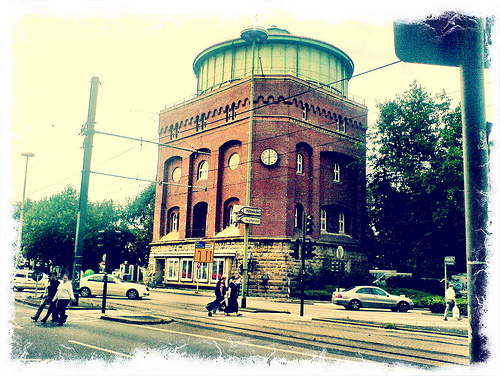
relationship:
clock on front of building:
[262, 147, 279, 168] [143, 23, 367, 299]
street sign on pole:
[232, 205, 262, 227] [240, 223, 250, 308]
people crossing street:
[32, 273, 75, 325] [13, 290, 471, 369]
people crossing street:
[207, 275, 242, 316] [13, 290, 471, 369]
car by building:
[331, 283, 414, 311] [143, 23, 367, 299]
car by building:
[79, 273, 151, 300] [143, 23, 367, 299]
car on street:
[331, 283, 414, 311] [13, 290, 471, 369]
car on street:
[79, 273, 151, 300] [13, 290, 471, 369]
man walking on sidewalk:
[441, 281, 460, 322] [313, 312, 473, 336]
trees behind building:
[13, 79, 463, 288] [143, 23, 367, 299]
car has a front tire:
[331, 283, 414, 311] [391, 302, 408, 313]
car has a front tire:
[79, 273, 151, 300] [127, 289, 141, 300]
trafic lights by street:
[290, 215, 317, 261] [13, 290, 471, 369]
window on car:
[357, 286, 386, 298] [331, 283, 414, 311]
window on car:
[89, 275, 116, 283] [79, 273, 151, 300]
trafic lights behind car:
[290, 215, 317, 261] [331, 283, 414, 311]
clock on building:
[262, 147, 279, 168] [143, 23, 367, 299]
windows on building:
[296, 152, 346, 235] [143, 23, 367, 299]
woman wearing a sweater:
[53, 275, 77, 327] [52, 279, 75, 302]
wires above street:
[13, 60, 493, 203] [13, 290, 471, 369]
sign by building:
[193, 241, 215, 265] [143, 23, 367, 299]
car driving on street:
[331, 283, 414, 311] [13, 290, 471, 369]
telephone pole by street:
[71, 77, 100, 304] [13, 290, 471, 369]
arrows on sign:
[197, 250, 214, 260] [193, 241, 215, 265]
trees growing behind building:
[13, 79, 463, 288] [143, 23, 367, 299]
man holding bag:
[441, 281, 460, 322] [451, 305, 460, 322]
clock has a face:
[262, 147, 279, 168] [263, 150, 276, 164]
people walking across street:
[32, 273, 75, 325] [13, 290, 471, 369]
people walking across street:
[207, 275, 242, 316] [13, 290, 471, 369]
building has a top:
[143, 23, 367, 299] [191, 23, 354, 97]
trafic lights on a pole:
[290, 215, 317, 261] [300, 211, 305, 315]